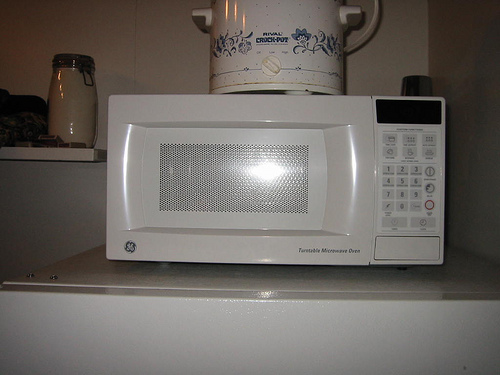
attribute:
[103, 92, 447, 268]
microwave — white 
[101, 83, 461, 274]
microwave — white